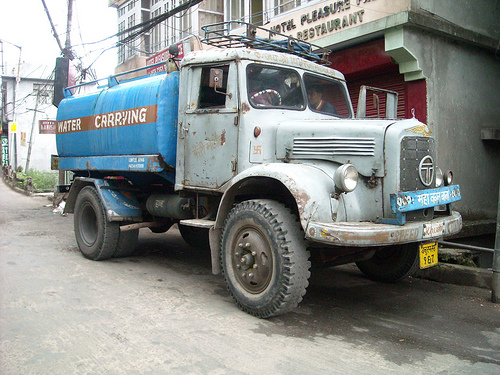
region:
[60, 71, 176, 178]
Blue tank on truck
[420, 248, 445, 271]
Yellow license plate on truck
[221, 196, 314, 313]
Front tire on truck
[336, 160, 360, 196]
Headlight on front of truck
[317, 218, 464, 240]
Bumper on front of truck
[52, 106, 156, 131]
Brown sign on truck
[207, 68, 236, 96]
Side mirror on truck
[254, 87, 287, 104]
Steering wheel in truck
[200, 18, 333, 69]
Rack on top of truck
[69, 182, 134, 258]
Rear tire on truck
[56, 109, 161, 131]
Words printed on the side of the truck.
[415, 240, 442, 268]
The yellow license plate.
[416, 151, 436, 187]
The silver logo on the truck.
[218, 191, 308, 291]
The right front tire.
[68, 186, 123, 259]
The back right tire.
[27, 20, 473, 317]
Large blue truck on the road.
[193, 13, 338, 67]
The blue rack on the truck.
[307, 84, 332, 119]
The man inside the truck.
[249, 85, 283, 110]
The steering wheel in the truck.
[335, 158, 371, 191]
The right front light.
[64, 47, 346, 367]
a truck on the road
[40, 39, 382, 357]
a truck on the street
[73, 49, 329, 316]
a road with a truck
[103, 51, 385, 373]
a street with a truck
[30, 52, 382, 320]
an old truck on the road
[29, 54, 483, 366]
an old truck on the street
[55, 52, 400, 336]
a street with an old truck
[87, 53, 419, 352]
a road with an old truck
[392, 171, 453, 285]
a truck with plates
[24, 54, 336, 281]
a water carrying truck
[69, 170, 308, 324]
tires on side of truck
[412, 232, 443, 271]
license plate on front of truck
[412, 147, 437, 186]
metal logo on front of truck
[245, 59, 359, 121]
windshield on front of truck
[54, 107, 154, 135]
white letters on side of truck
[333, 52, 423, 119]
red garage behind truck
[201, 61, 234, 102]
rear view mirror on side of truck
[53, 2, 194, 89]
power lines above truck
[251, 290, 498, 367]
stain on street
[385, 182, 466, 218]
blue rectangular sign on front of truck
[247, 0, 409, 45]
a sign advertising a restaurant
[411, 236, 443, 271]
the license plate is yellow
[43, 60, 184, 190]
this tank contains water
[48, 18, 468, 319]
this truck has been around for a lot of years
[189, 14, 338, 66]
a rack mounted on top of the truck cab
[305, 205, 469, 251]
the rusty bumper of the truck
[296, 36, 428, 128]
the front of the restaurant is painted maroon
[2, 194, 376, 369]
truck sits on a pockmarked street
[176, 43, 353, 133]
a European design with steering wheel on the right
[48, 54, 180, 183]
the water tank is painted blue